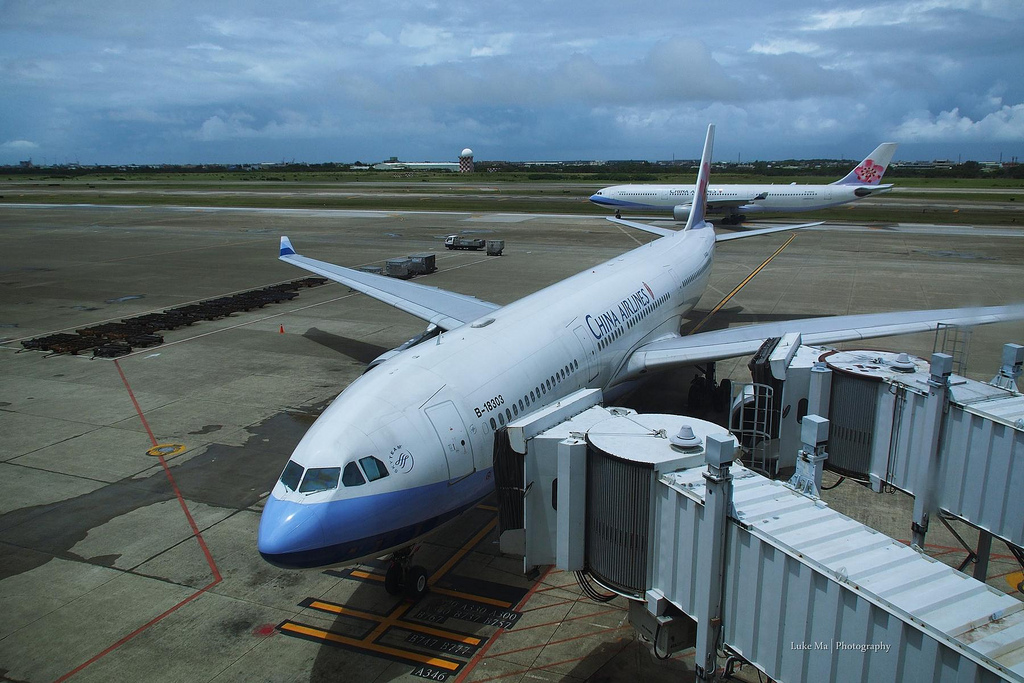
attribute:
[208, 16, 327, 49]
cloud — white 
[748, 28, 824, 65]
cloud — white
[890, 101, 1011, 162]
cloud — white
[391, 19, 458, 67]
cloud — white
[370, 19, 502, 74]
cloud — white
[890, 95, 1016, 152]
cloud — white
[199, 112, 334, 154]
cloud — white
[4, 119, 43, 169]
cloud — white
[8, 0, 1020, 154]
clouds — white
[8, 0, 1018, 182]
clouds — white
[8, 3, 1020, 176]
sky — blue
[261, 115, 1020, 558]
plane — white, blue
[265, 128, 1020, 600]
airplane — blue, white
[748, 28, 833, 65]
cloud — white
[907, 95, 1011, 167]
cloud — white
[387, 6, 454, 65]
cloud — white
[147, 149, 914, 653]
plane — white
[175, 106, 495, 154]
clouds — white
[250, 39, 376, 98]
clouds — white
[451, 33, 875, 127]
clodus — white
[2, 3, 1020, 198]
sky — blue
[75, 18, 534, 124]
cloud — white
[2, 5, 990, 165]
sky — blue 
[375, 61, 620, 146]
cloud — white